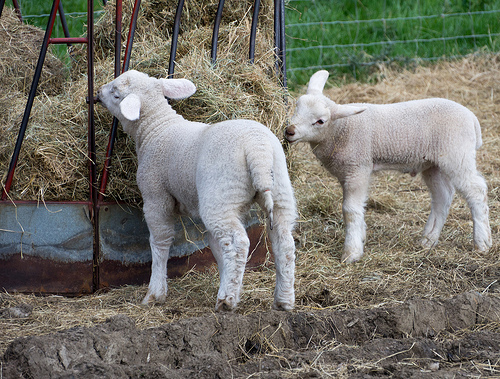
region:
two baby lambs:
[86, 50, 499, 297]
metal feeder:
[32, 6, 315, 268]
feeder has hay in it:
[23, 14, 294, 236]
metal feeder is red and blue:
[45, 12, 331, 285]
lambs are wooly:
[105, 75, 497, 318]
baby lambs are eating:
[71, 72, 497, 330]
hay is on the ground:
[330, 215, 478, 308]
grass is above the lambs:
[294, 12, 481, 52]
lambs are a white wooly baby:
[63, 70, 497, 286]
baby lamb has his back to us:
[93, 48, 329, 312]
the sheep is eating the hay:
[71, 56, 321, 317]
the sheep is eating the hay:
[268, 88, 498, 239]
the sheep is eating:
[248, 83, 497, 263]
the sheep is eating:
[73, 56, 215, 195]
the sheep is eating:
[275, 75, 342, 185]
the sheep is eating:
[228, 55, 353, 201]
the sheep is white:
[87, 38, 314, 316]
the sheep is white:
[262, 60, 495, 302]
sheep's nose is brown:
[288, 112, 305, 156]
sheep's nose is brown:
[277, 108, 314, 161]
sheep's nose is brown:
[277, 109, 337, 184]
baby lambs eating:
[20, 13, 495, 374]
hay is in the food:
[2, 20, 452, 374]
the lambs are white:
[82, 28, 473, 316]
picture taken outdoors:
[88, 83, 478, 377]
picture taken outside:
[35, 43, 477, 347]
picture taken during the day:
[31, 40, 461, 367]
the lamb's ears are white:
[92, 55, 230, 140]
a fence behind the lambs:
[314, 16, 484, 80]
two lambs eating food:
[98, 59, 490, 313]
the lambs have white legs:
[107, 160, 395, 315]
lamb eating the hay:
[283, 78, 487, 263]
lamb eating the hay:
[99, 68, 284, 293]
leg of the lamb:
[207, 226, 250, 318]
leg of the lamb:
[261, 213, 302, 310]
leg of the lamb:
[148, 210, 182, 311]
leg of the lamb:
[328, 183, 361, 265]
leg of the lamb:
[413, 192, 435, 247]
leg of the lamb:
[462, 180, 497, 257]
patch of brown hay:
[368, 261, 395, 287]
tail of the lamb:
[467, 123, 485, 148]